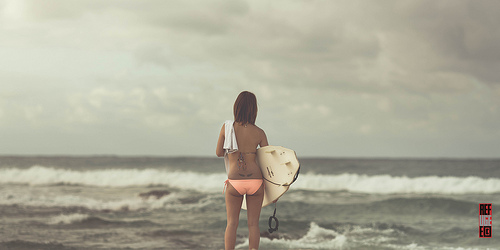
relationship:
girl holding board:
[215, 91, 270, 250] [241, 145, 301, 210]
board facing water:
[235, 142, 303, 213] [0, 153, 499, 247]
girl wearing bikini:
[214, 88, 302, 249] [223, 141, 263, 198]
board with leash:
[241, 145, 301, 210] [266, 206, 283, 237]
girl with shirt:
[214, 88, 302, 249] [222, 119, 241, 154]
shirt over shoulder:
[222, 119, 241, 154] [222, 122, 238, 132]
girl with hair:
[214, 88, 302, 249] [231, 90, 260, 124]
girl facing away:
[214, 88, 302, 249] [2, 0, 499, 247]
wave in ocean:
[3, 158, 500, 223] [2, 147, 500, 247]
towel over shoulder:
[222, 118, 238, 157] [222, 122, 238, 132]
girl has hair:
[215, 91, 270, 250] [231, 90, 260, 124]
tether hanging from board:
[267, 203, 279, 235] [241, 145, 301, 210]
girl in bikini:
[215, 91, 270, 250] [223, 141, 263, 198]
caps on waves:
[3, 158, 499, 191] [4, 161, 499, 228]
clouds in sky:
[7, 5, 500, 146] [5, 5, 494, 155]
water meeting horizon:
[0, 153, 499, 247] [3, 0, 500, 156]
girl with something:
[215, 91, 270, 250] [223, 117, 235, 155]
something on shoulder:
[223, 117, 235, 155] [222, 122, 238, 132]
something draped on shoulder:
[223, 117, 235, 155] [222, 122, 238, 132]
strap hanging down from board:
[267, 210, 282, 237] [241, 145, 301, 210]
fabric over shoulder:
[222, 118, 239, 155] [222, 122, 238, 132]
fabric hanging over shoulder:
[222, 118, 239, 155] [222, 122, 238, 132]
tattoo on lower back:
[235, 171, 256, 178] [230, 169, 262, 179]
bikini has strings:
[223, 141, 263, 198] [234, 152, 248, 169]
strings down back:
[234, 152, 248, 169] [230, 123, 258, 178]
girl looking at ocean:
[215, 91, 270, 250] [2, 147, 500, 247]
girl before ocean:
[214, 88, 302, 249] [2, 147, 500, 247]